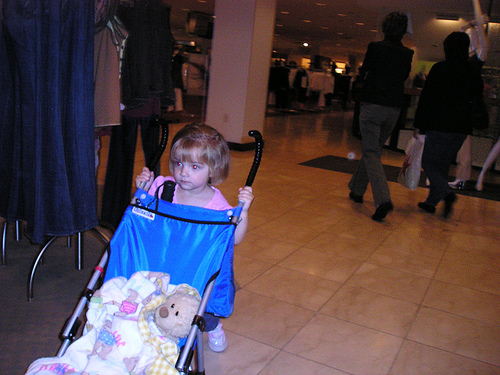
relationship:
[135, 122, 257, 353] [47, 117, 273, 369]
child pushing stroller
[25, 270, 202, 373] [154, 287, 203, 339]
baby blankets covers animal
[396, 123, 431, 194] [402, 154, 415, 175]
bag has star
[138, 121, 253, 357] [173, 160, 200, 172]
child has eyes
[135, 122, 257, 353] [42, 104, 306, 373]
child push stroller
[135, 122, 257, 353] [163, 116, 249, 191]
child has hair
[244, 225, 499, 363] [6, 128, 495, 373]
tiles on ground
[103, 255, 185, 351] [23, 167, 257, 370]
animal on stroller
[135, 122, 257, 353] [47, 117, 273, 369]
child push stroller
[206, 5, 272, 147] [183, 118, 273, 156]
pillar in center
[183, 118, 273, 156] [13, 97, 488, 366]
center of walkway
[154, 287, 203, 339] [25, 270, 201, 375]
animal under baby blankets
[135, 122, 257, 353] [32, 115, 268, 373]
child pushing stroller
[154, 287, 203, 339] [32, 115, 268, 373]
animal in stroller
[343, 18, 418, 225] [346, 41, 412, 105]
woman with jacket